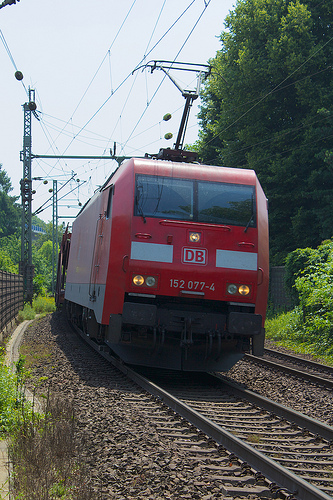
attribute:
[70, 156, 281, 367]
train — these, red, powered, centered, here, white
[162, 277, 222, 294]
152 077-4 — number, white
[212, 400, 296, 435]
tracks — metal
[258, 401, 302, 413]
bed — gravel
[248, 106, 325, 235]
trees — high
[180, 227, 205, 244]
headlamp — four, on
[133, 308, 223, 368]
bumper — black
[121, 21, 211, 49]
wires — electric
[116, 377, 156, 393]
plank — wood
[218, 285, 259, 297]
lights — signal, orange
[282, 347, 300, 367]
gravel — gray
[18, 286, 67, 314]
bushes — green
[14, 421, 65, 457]
weed — different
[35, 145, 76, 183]
pole — metal